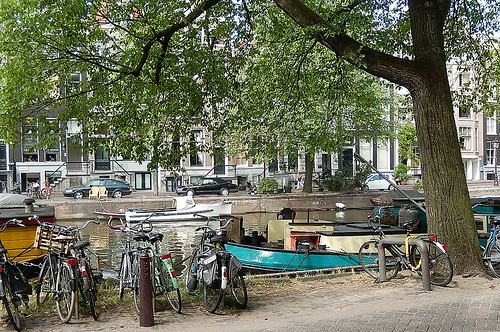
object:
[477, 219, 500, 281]
bicycle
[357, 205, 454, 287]
bicycle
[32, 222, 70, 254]
basket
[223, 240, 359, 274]
boat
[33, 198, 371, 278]
water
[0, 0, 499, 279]
tree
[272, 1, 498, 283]
trunk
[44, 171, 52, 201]
people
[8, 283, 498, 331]
sidewalk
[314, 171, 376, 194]
bushes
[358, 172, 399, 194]
car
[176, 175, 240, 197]
car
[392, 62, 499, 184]
building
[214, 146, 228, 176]
door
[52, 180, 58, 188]
stairs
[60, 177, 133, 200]
van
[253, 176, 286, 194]
plant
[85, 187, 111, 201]
seats